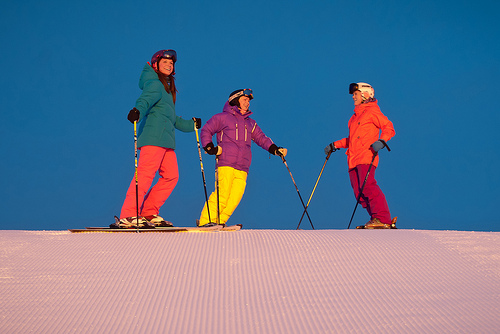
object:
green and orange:
[117, 63, 195, 219]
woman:
[197, 89, 287, 229]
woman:
[324, 81, 397, 231]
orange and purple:
[332, 99, 395, 226]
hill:
[1, 229, 500, 334]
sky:
[1, 1, 500, 231]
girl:
[324, 80, 395, 231]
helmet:
[348, 82, 374, 102]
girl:
[196, 89, 282, 229]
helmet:
[228, 88, 254, 107]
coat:
[200, 101, 275, 174]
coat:
[133, 61, 196, 152]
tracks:
[1, 228, 500, 333]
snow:
[1, 228, 498, 333]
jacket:
[131, 61, 196, 151]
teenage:
[109, 50, 202, 230]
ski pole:
[132, 117, 139, 231]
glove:
[126, 108, 140, 124]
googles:
[162, 49, 177, 61]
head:
[152, 49, 179, 76]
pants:
[347, 163, 394, 226]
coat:
[332, 100, 396, 172]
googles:
[349, 83, 359, 95]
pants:
[199, 166, 247, 226]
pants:
[118, 145, 180, 220]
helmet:
[150, 49, 177, 64]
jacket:
[200, 101, 279, 175]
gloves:
[324, 142, 338, 155]